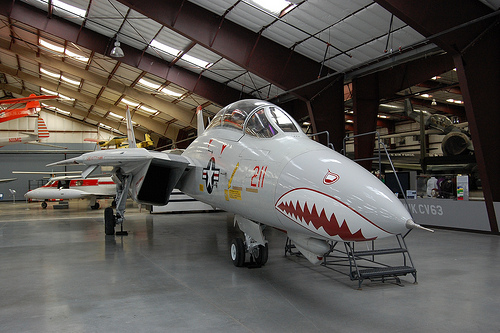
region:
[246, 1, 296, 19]
lit ceiling light in large building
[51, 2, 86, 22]
lit ceiling light in large building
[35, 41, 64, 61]
lit ceiling light in large building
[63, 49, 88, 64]
lit ceiling light in large building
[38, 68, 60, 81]
lit ceiling light in large building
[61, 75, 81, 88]
lit ceiling light in large building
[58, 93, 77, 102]
lit ceiling light in large building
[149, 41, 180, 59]
lit ceiling light in large building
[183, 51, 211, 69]
lit ceiling light in large building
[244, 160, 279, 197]
the numbers 211 on plane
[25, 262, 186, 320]
shiny grey concrete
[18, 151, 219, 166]
the wing on a plane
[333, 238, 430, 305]
grey metal steps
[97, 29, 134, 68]
a light hanging from celing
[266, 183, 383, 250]
red and white paint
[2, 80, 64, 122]
a red plane on cewling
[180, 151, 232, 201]
a black and white star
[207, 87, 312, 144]
a clear windshield on plane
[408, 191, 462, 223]
letters and number on wall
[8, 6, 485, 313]
planes and jets on display in hangar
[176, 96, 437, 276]
jet painted to look like gray shark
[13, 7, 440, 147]
large slanted roof with light panels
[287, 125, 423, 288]
gray metal ladder behind jet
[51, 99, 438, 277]
a grey fighter jet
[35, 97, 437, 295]
a jet painted like a shark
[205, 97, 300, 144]
cockpit of a fighter jet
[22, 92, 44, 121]
a red tail wing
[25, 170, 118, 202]
a red and white plane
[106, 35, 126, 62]
a hanging ceiling light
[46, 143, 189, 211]
the wing of a fighter jet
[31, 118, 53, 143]
a red and white tail wing of a plane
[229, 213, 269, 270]
landing gear wheels on a jet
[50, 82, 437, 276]
A parked gray fighter jet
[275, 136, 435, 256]
Shark face on fighter plane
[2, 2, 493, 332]
Large hanger for planes